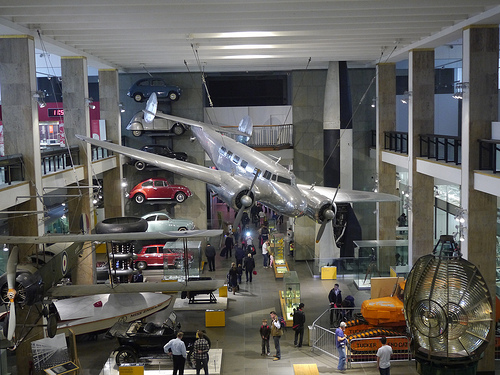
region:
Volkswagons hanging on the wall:
[121, 73, 196, 269]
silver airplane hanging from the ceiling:
[78, 98, 405, 234]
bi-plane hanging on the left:
[3, 211, 229, 341]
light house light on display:
[401, 231, 496, 371]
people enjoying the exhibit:
[229, 216, 283, 359]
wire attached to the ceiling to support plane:
[173, 37, 403, 72]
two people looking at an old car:
[102, 315, 217, 372]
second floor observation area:
[377, 115, 497, 185]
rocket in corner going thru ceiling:
[311, 53, 368, 270]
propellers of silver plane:
[227, 167, 347, 248]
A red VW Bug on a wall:
[124, 174, 194, 209]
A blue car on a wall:
[122, 71, 186, 108]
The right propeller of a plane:
[219, 162, 279, 243]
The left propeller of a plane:
[302, 178, 355, 251]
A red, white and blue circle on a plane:
[52, 249, 79, 282]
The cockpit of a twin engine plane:
[260, 163, 315, 229]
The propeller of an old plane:
[2, 239, 36, 347]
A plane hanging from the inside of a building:
[72, 83, 412, 250]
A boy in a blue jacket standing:
[254, 317, 274, 361]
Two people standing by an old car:
[158, 327, 218, 374]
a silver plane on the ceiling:
[80, 105, 407, 242]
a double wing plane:
[2, 225, 223, 320]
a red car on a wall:
[125, 175, 190, 205]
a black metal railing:
[420, 131, 459, 161]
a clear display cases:
[281, 273, 301, 327]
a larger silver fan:
[401, 241, 493, 356]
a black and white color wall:
[324, 68, 353, 183]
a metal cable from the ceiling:
[322, 33, 401, 172]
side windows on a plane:
[218, 148, 253, 177]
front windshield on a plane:
[263, 165, 295, 192]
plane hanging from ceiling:
[0, 72, 448, 273]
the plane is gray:
[2, 76, 429, 264]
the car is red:
[111, 176, 201, 214]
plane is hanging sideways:
[5, 61, 405, 245]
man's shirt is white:
[148, 331, 191, 358]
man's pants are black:
[166, 352, 183, 373]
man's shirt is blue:
[332, 326, 347, 346]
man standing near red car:
[196, 231, 219, 273]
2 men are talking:
[163, 328, 213, 373]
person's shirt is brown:
[264, 315, 291, 345]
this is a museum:
[150, 110, 395, 362]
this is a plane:
[109, 71, 396, 246]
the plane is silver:
[208, 126, 325, 273]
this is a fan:
[371, 239, 464, 331]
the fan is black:
[421, 253, 466, 339]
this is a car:
[138, 178, 189, 215]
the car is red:
[113, 123, 231, 264]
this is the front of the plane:
[231, 139, 339, 276]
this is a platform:
[368, 89, 493, 184]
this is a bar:
[46, 113, 49, 178]